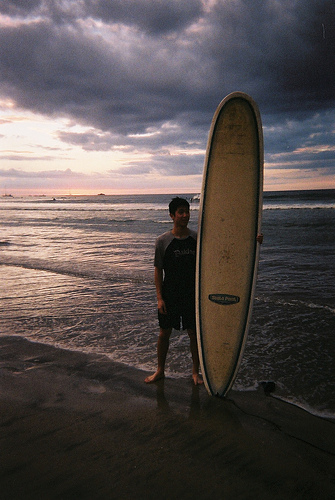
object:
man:
[143, 195, 205, 385]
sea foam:
[0, 320, 335, 422]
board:
[194, 88, 265, 397]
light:
[0, 261, 87, 316]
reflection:
[1, 218, 151, 275]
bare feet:
[143, 369, 168, 384]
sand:
[0, 334, 335, 499]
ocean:
[0, 200, 335, 421]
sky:
[1, 1, 335, 195]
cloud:
[0, 0, 335, 181]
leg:
[157, 309, 175, 375]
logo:
[207, 290, 240, 306]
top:
[211, 89, 265, 137]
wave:
[0, 244, 155, 288]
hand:
[155, 293, 167, 310]